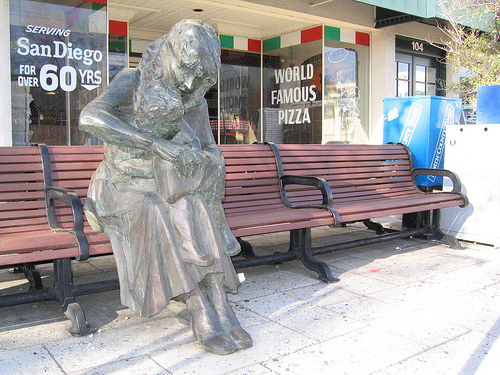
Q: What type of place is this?
A: It is a sidewalk.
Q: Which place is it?
A: It is a sidewalk.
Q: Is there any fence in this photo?
A: No, there are no fences.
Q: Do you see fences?
A: No, there are no fences.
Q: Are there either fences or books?
A: No, there are no fences or books.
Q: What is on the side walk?
A: The benches are on the side walk.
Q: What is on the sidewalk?
A: The benches are on the side walk.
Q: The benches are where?
A: The benches are on the sidewalk.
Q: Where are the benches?
A: The benches are on the sidewalk.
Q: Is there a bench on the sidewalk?
A: Yes, there are benches on the sidewalk.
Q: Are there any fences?
A: No, there are no fences.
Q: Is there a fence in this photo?
A: No, there are no fences.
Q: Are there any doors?
A: Yes, there is a door.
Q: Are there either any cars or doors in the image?
A: Yes, there is a door.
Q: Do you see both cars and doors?
A: No, there is a door but no cars.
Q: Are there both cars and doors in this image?
A: No, there is a door but no cars.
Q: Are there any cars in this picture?
A: No, there are no cars.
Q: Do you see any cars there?
A: No, there are no cars.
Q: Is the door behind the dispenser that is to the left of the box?
A: Yes, the door is behind the dispenser.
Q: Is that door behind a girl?
A: No, the door is behind the dispenser.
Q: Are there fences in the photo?
A: No, there are no fences.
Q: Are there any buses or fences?
A: No, there are no fences or buses.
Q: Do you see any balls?
A: No, there are no balls.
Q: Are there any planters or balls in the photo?
A: No, there are no balls or planters.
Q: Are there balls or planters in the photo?
A: No, there are no balls or planters.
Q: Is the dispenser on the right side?
A: Yes, the dispenser is on the right of the image.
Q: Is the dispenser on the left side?
A: No, the dispenser is on the right of the image.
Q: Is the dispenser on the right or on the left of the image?
A: The dispenser is on the right of the image.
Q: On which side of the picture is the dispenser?
A: The dispenser is on the right of the image.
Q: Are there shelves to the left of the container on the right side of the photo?
A: No, there is a dispenser to the left of the box.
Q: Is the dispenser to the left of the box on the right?
A: Yes, the dispenser is to the left of the box.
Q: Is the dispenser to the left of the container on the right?
A: Yes, the dispenser is to the left of the box.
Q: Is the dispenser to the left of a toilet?
A: No, the dispenser is to the left of the box.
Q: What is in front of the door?
A: The dispenser is in front of the door.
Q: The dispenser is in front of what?
A: The dispenser is in front of the door.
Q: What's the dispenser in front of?
A: The dispenser is in front of the door.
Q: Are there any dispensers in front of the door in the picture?
A: Yes, there is a dispenser in front of the door.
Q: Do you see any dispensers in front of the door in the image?
A: Yes, there is a dispenser in front of the door.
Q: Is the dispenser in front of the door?
A: Yes, the dispenser is in front of the door.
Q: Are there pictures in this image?
A: No, there are no pictures.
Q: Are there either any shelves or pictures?
A: No, there are no pictures or shelves.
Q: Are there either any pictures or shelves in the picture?
A: No, there are no pictures or shelves.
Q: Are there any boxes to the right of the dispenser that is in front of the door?
A: Yes, there is a box to the right of the dispenser.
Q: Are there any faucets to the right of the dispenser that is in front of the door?
A: No, there is a box to the right of the dispenser.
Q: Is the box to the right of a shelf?
A: No, the box is to the right of a dispenser.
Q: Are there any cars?
A: No, there are no cars.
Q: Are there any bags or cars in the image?
A: No, there are no cars or bags.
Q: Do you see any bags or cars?
A: No, there are no cars or bags.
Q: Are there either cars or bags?
A: No, there are no cars or bags.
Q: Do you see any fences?
A: No, there are no fences.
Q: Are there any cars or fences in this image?
A: No, there are no fences or cars.